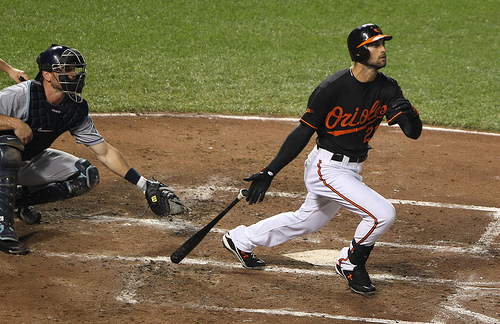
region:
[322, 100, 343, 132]
The letter is orange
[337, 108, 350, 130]
The letter is orange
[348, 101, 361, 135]
The letter is orange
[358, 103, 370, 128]
The letter is orange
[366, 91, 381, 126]
The letter is orange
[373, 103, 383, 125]
The letter is orange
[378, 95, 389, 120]
The letter is orange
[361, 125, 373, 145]
The number is orange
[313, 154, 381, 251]
The stripe is orange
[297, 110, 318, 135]
The stripe is orange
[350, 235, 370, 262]
ankle protection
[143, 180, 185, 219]
a black catchers glove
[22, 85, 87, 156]
a Nike protection gear on the catcher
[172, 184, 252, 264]
a black baseball bat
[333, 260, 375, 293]
black baseball cleats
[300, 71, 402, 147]
a black jersey with orange writing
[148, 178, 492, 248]
batter's box lined with chalk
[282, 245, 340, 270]
the home plate has dirt on it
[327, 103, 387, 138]
the team name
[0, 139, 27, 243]
knee and shin protection gear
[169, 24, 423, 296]
A baseball player has swung the bat.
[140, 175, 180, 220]
A baseball mitt is black.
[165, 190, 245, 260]
A bat is black and white.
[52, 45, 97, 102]
A face is protected by a mask.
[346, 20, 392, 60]
A head is wearing a batting helmet.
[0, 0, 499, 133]
The grass is green.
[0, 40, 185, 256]
A catcher is in his stance for catching.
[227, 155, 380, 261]
The pants are white with an orange stripe.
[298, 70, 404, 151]
The shirt is for the Orioles.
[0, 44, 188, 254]
A hand is behind a catcher's head.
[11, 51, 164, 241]
a catcher of the baseball game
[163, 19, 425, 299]
a man dropping a baseball bat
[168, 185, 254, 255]
a black baseball bat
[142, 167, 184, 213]
a black baseball mitt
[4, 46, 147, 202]
a person wearing a grey shirt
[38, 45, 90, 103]
the helmet the catcher is wearing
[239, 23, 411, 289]
a man wearing a black shirt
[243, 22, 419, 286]
a man wearing black gloves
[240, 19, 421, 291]
a man wearing white pants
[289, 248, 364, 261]
the home plate on the field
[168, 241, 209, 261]
a baseball bat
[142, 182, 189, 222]
a baseball mit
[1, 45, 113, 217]
the catcher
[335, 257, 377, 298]
the baseball player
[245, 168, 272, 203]
a black glove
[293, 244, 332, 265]
a white plate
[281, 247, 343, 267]
home plate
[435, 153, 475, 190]
the dirt is brown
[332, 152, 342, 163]
black belt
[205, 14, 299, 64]
the green grass in the field